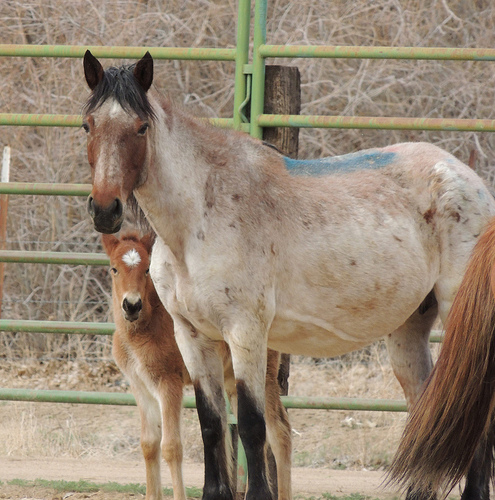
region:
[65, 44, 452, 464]
a goat and a young one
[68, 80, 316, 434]
the goats are staring in open air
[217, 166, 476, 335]
goat is white in color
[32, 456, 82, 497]
floor has grasses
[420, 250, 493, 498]
tail of another animal at the edge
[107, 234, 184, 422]
young goat is brown in color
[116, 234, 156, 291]
goat has a white spot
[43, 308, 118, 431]
the fence is rusted green incolor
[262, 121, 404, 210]
goat has a blue mark on the bark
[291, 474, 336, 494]
a dry grass field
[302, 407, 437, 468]
a dry grass field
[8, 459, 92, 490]
a dry grass field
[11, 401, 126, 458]
a dry grass field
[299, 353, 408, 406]
a dry grass field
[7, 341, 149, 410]
a dry grass field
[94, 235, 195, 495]
A small baby donkey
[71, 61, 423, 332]
A bown big donkey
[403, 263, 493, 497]
A bown big donkey's tail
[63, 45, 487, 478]
An adult and baby horse in a pen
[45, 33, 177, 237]
the horse is looking at the camera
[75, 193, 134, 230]
the nose is black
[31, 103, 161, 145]
the eyes are open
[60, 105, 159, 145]
the eyes are black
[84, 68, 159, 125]
the hair is black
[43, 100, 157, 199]
the face is brown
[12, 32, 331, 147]
the fence is behind the horse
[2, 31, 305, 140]
the fence is green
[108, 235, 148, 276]
a white patch on the horses forehead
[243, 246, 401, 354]
the stomach is white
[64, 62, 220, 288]
face of the horse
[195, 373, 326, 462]
front legs of the horse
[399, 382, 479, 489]
tail of the harse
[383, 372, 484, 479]
part of the tail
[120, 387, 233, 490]
another legs of the horse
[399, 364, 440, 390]
back leg of the h orse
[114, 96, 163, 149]
eye of the horse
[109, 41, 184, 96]
ear of the horse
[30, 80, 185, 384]
horse and cow in ground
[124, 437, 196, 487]
legs of the cow